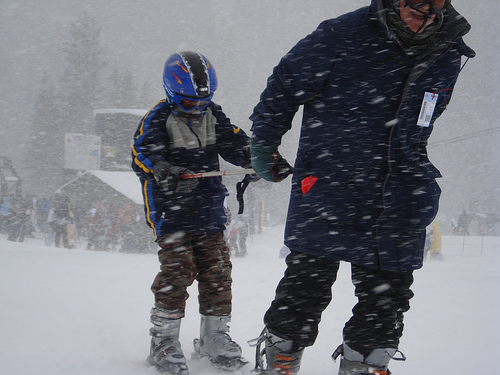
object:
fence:
[432, 223, 497, 260]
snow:
[1, 1, 499, 373]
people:
[0, 189, 32, 239]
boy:
[130, 49, 284, 374]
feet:
[143, 322, 191, 374]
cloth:
[130, 101, 272, 233]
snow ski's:
[195, 316, 248, 375]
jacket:
[254, 2, 476, 276]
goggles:
[164, 90, 211, 113]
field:
[2, 240, 497, 372]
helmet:
[156, 50, 221, 124]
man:
[240, 0, 495, 375]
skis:
[140, 305, 188, 375]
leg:
[149, 223, 197, 339]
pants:
[153, 215, 236, 324]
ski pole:
[179, 164, 298, 179]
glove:
[246, 134, 301, 184]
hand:
[250, 140, 290, 182]